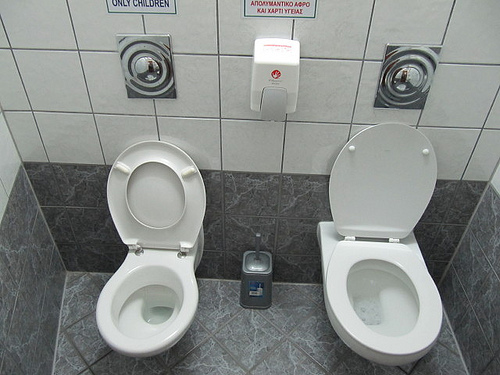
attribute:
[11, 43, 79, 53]
grout line — dark grey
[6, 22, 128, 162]
wall — white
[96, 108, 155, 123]
line — dark grey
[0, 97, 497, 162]
line — dark grey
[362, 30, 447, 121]
flush button — silver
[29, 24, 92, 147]
tiles — gray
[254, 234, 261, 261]
brush — gray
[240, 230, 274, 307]
bowl — plastic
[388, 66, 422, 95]
button — chrome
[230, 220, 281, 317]
cleaner — grey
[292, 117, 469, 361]
toilet — white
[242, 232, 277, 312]
toilet brush — grey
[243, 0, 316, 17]
sign — red, white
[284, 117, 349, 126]
line — dark grey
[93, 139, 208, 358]
toilet — white, child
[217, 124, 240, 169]
grout — dark grey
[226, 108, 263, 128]
line — dark grey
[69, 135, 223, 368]
toilet — child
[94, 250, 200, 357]
toilet bowl — white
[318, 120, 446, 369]
toilet — adult, white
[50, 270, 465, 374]
floor — gray, tiled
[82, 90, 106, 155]
grout line — dark grey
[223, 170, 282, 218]
tile — grey, marble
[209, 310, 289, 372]
tile — marble, grey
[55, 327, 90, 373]
tile — marble, grey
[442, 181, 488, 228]
tile — marble, grey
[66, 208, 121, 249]
tile — marble, grey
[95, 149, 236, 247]
seat — up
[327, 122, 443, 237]
lid — open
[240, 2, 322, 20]
sign — white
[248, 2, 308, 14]
lettering — red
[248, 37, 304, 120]
dispenser — white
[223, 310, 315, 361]
tiles — white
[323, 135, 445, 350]
toilet — white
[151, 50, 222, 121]
tile — white, wall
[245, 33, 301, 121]
dispenser — white, red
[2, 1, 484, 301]
wall — tile